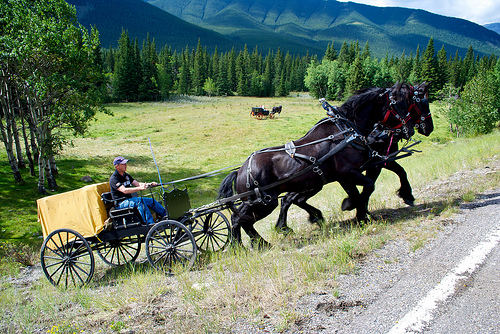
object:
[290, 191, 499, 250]
shadow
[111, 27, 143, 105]
tree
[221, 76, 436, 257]
pair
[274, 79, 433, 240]
horses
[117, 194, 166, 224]
blue jeans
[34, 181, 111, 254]
box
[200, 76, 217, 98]
trees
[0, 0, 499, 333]
background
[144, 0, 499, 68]
range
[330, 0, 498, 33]
distance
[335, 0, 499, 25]
sky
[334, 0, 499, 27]
clouds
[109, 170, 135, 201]
shirt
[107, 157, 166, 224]
man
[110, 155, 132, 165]
cap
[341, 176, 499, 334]
edge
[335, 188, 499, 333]
road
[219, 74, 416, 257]
horses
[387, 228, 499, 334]
line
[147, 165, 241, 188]
bridle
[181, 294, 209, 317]
weeds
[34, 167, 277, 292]
wagon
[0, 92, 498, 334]
field